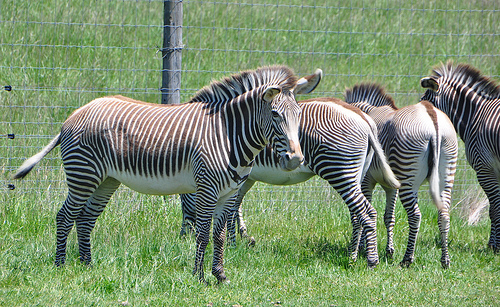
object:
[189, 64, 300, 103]
zebra mane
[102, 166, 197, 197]
belly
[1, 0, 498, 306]
grass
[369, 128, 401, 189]
tail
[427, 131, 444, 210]
tail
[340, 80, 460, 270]
zebra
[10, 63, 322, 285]
zebra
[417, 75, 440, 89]
ear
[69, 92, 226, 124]
back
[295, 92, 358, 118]
back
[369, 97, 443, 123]
back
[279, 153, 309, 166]
nose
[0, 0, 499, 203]
fence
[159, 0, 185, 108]
wooden pole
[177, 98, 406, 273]
zebra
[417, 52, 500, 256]
zebra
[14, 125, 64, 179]
tail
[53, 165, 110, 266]
leg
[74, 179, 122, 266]
leg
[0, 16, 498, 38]
wire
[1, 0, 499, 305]
field